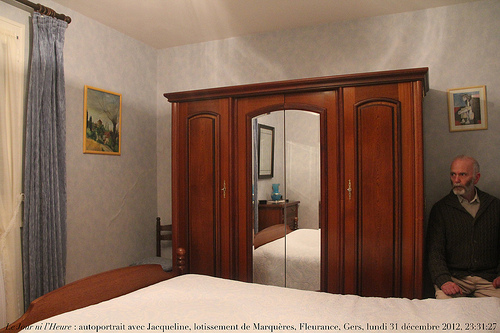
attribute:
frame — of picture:
[83, 82, 123, 160]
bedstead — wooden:
[2, 246, 483, 331]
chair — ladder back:
[127, 212, 181, 272]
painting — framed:
[77, 76, 123, 157]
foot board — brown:
[3, 245, 190, 331]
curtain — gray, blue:
[21, 12, 71, 322]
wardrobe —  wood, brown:
[161, 63, 429, 301]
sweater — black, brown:
[423, 186, 483, 288]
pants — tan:
[432, 275, 484, 300]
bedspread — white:
[20, 272, 484, 331]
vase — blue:
[268, 179, 284, 202]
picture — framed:
[442, 84, 484, 132]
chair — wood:
[127, 215, 175, 274]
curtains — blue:
[24, 12, 72, 306]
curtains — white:
[1, 29, 28, 329]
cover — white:
[20, 269, 484, 329]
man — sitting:
[428, 145, 473, 280]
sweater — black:
[428, 191, 490, 268]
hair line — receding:
[455, 157, 475, 167]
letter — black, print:
[58, 320, 138, 330]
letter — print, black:
[53, 320, 173, 331]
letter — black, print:
[95, 319, 240, 329]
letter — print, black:
[126, 316, 304, 331]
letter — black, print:
[128, 318, 214, 331]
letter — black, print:
[213, 320, 298, 331]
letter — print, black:
[219, 319, 326, 330]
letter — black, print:
[267, 320, 369, 330]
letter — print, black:
[323, 322, 397, 331]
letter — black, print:
[386, 320, 449, 330]